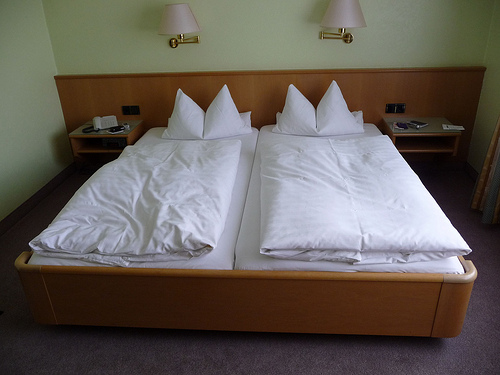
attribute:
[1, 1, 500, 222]
wall — off white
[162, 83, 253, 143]
pillow — white, bent, fluffy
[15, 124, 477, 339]
bed — white, wooden, king size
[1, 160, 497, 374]
carpet — gray, dark purple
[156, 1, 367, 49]
lights — small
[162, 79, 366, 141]
pillows — white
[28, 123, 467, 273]
mattresses — twin size, together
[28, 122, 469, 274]
sheets — white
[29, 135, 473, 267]
blankets — white, folded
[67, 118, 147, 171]
night stand — brown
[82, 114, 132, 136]
objects — various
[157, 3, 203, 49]
light — small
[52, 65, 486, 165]
headboard — wooden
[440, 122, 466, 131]
paper — white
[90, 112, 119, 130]
telephone — white